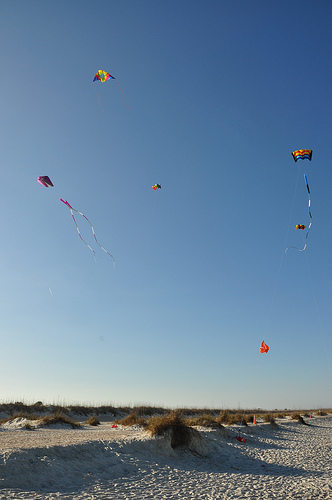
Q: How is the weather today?
A: It is clear.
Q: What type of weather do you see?
A: It is clear.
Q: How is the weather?
A: It is clear.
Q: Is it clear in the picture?
A: Yes, it is clear.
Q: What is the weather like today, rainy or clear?
A: It is clear.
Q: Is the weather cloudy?
A: No, it is clear.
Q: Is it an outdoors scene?
A: Yes, it is outdoors.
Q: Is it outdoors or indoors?
A: It is outdoors.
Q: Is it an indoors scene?
A: No, it is outdoors.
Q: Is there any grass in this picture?
A: Yes, there is grass.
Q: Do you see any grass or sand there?
A: Yes, there is grass.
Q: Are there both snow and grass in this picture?
A: No, there is grass but no snow.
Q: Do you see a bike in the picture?
A: No, there are no bikes.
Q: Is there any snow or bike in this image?
A: No, there are no bikes or snow.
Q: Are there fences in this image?
A: No, there are no fences.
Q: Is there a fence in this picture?
A: No, there are no fences.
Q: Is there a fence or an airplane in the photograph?
A: No, there are no fences or airplanes.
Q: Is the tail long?
A: Yes, the tail is long.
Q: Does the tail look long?
A: Yes, the tail is long.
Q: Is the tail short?
A: No, the tail is long.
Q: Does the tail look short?
A: No, the tail is long.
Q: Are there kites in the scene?
A: Yes, there is a kite.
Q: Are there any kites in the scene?
A: Yes, there is a kite.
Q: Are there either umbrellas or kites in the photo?
A: Yes, there is a kite.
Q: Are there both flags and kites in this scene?
A: No, there is a kite but no flags.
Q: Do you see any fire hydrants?
A: No, there are no fire hydrants.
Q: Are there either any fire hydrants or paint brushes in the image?
A: No, there are no fire hydrants or paint brushes.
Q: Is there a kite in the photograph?
A: Yes, there is a kite.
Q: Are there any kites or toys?
A: Yes, there is a kite.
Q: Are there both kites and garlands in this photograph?
A: No, there is a kite but no garlands.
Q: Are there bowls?
A: No, there are no bowls.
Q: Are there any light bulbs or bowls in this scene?
A: No, there are no bowls or light bulbs.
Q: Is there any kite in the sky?
A: Yes, there is a kite in the sky.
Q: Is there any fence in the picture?
A: No, there are no fences.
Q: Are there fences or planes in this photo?
A: No, there are no fences or planes.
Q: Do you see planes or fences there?
A: No, there are no fences or planes.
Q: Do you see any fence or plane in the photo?
A: No, there are no fences or airplanes.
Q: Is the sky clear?
A: Yes, the sky is clear.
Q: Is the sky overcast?
A: No, the sky is clear.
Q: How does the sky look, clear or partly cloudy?
A: The sky is clear.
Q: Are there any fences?
A: No, there are no fences.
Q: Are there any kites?
A: Yes, there is a kite.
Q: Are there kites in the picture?
A: Yes, there is a kite.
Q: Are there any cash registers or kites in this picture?
A: Yes, there is a kite.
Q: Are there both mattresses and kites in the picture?
A: No, there is a kite but no mattresses.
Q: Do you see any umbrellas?
A: No, there are no umbrellas.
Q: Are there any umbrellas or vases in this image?
A: No, there are no umbrellas or vases.